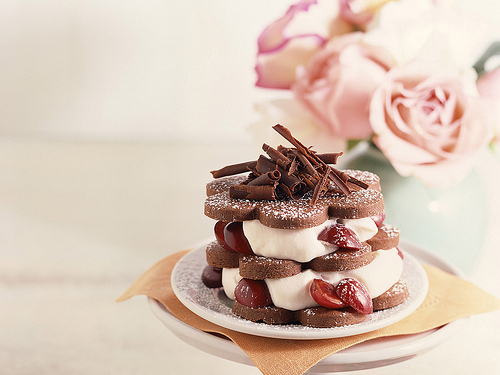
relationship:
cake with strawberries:
[200, 124, 408, 328] [310, 218, 373, 303]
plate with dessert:
[139, 260, 397, 339] [181, 144, 404, 345]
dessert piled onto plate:
[200, 122, 408, 329] [170, 243, 429, 340]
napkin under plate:
[252, 349, 290, 373] [233, 314, 293, 342]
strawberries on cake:
[307, 285, 350, 306] [195, 124, 433, 345]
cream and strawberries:
[365, 270, 391, 289] [303, 269, 357, 314]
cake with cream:
[210, 121, 417, 337] [369, 259, 396, 291]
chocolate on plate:
[245, 176, 286, 206] [166, 268, 216, 308]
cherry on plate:
[333, 276, 373, 317] [168, 265, 225, 333]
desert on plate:
[184, 154, 410, 354] [172, 270, 222, 330]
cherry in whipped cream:
[319, 224, 363, 250] [241, 218, 379, 264]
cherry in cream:
[232, 275, 274, 308] [219, 248, 401, 312]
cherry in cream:
[307, 279, 347, 309] [219, 248, 401, 312]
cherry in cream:
[333, 276, 373, 317] [219, 248, 401, 312]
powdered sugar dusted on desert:
[205, 168, 377, 219] [198, 122, 408, 326]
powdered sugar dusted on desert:
[240, 254, 292, 270] [198, 122, 408, 326]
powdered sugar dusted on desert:
[324, 227, 367, 259] [198, 122, 408, 326]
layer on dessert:
[204, 239, 408, 328] [200, 122, 408, 329]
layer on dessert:
[205, 168, 400, 279] [200, 122, 408, 329]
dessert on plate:
[200, 122, 408, 329] [170, 243, 429, 340]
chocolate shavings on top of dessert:
[209, 123, 369, 203] [200, 122, 408, 329]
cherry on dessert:
[333, 276, 373, 317] [200, 122, 408, 329]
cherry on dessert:
[307, 278, 347, 308] [200, 122, 408, 329]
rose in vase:
[365, 60, 497, 191] [340, 141, 498, 276]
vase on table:
[340, 141, 498, 276] [1, 132, 499, 372]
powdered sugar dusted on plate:
[176, 239, 237, 314] [167, 238, 431, 345]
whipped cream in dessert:
[241, 218, 379, 264] [200, 122, 408, 329]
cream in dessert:
[219, 248, 401, 312] [200, 122, 408, 329]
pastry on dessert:
[202, 166, 386, 230] [200, 122, 408, 329]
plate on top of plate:
[170, 243, 429, 340] [145, 241, 465, 365]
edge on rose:
[251, 0, 328, 91] [365, 60, 497, 191]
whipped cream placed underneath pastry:
[241, 218, 379, 264] [202, 167, 386, 230]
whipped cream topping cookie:
[241, 218, 379, 264] [203, 222, 401, 281]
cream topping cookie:
[219, 248, 401, 312] [231, 279, 410, 329]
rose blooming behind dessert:
[365, 51, 483, 190] [200, 122, 408, 329]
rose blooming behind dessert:
[287, 26, 398, 141] [200, 122, 408, 329]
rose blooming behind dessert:
[249, 1, 355, 92] [200, 122, 408, 329]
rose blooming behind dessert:
[342, 1, 388, 24] [200, 122, 408, 329]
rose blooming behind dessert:
[368, 2, 454, 63] [200, 122, 408, 329]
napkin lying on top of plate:
[114, 245, 500, 375] [145, 235, 473, 372]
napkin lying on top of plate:
[114, 245, 500, 375] [145, 241, 465, 365]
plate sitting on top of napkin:
[170, 243, 429, 340] [114, 245, 500, 375]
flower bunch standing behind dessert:
[251, 0, 479, 190] [200, 122, 408, 329]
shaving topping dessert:
[272, 122, 352, 197] [200, 122, 408, 329]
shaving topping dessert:
[225, 183, 276, 201] [200, 122, 408, 329]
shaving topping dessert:
[243, 167, 281, 185] [200, 122, 408, 329]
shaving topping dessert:
[308, 162, 332, 208] [200, 122, 408, 329]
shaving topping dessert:
[254, 157, 299, 188] [200, 122, 408, 329]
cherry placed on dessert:
[333, 276, 373, 317] [200, 122, 408, 329]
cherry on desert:
[317, 224, 363, 251] [223, 140, 403, 367]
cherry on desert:
[232, 278, 274, 308] [217, 141, 399, 341]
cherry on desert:
[221, 222, 253, 258] [229, 148, 423, 362]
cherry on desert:
[221, 241, 234, 258] [199, 142, 411, 348]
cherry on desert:
[188, 267, 212, 287] [206, 142, 404, 319]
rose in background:
[365, 60, 497, 191] [106, 142, 494, 193]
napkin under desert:
[114, 245, 500, 375] [199, 119, 387, 291]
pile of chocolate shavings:
[231, 132, 346, 212] [260, 134, 311, 205]